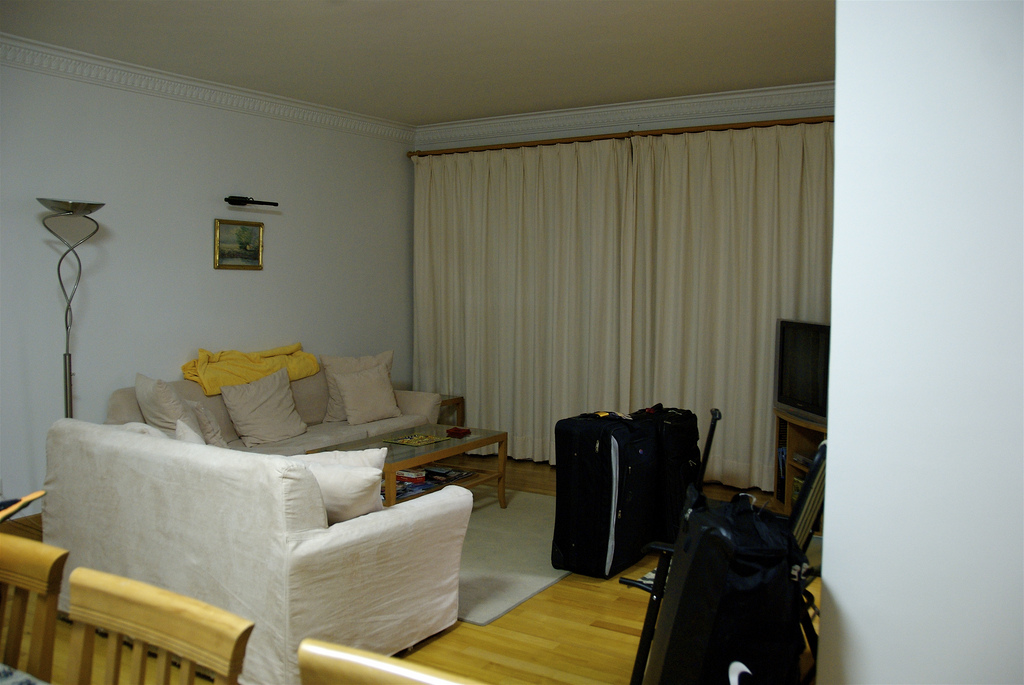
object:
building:
[7, 0, 1024, 685]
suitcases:
[629, 494, 816, 685]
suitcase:
[553, 411, 650, 581]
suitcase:
[622, 403, 707, 548]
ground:
[0, 455, 827, 685]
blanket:
[183, 342, 322, 396]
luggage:
[625, 500, 819, 684]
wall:
[814, 2, 1024, 685]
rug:
[458, 484, 575, 627]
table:
[306, 423, 509, 510]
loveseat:
[43, 417, 475, 685]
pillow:
[287, 446, 389, 522]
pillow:
[332, 363, 401, 425]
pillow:
[221, 368, 308, 448]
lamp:
[36, 197, 104, 421]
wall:
[0, 34, 411, 519]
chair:
[47, 566, 252, 684]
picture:
[214, 219, 264, 270]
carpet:
[458, 485, 571, 627]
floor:
[391, 454, 821, 684]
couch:
[110, 342, 439, 456]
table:
[0, 660, 54, 684]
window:
[411, 120, 834, 493]